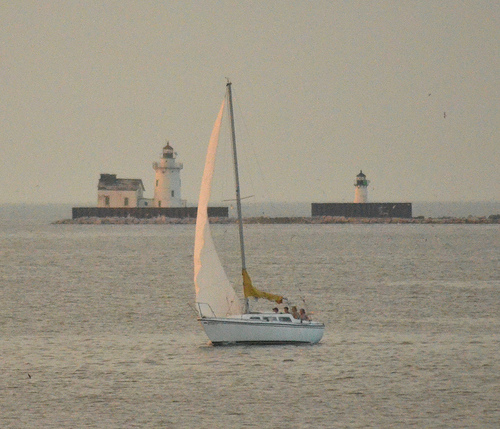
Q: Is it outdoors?
A: Yes, it is outdoors.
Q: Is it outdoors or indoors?
A: It is outdoors.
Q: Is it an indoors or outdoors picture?
A: It is outdoors.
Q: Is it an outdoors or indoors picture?
A: It is outdoors.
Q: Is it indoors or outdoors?
A: It is outdoors.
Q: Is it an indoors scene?
A: No, it is outdoors.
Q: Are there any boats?
A: Yes, there is a boat.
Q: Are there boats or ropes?
A: Yes, there is a boat.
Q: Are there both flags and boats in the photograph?
A: Yes, there are both a boat and a flag.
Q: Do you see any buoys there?
A: No, there are no buoys.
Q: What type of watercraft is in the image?
A: The watercraft is a boat.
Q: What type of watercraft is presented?
A: The watercraft is a boat.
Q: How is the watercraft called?
A: The watercraft is a boat.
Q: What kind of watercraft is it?
A: The watercraft is a boat.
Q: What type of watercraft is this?
A: This is a boat.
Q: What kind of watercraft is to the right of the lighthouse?
A: The watercraft is a boat.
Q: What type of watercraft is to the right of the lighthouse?
A: The watercraft is a boat.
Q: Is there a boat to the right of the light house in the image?
A: Yes, there is a boat to the right of the light house.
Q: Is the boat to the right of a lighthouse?
A: Yes, the boat is to the right of a lighthouse.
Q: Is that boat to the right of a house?
A: No, the boat is to the right of a lighthouse.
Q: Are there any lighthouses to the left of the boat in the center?
A: Yes, there is a lighthouse to the left of the boat.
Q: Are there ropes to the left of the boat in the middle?
A: No, there is a lighthouse to the left of the boat.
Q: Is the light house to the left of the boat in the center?
A: Yes, the light house is to the left of the boat.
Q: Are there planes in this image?
A: No, there are no planes.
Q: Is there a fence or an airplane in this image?
A: No, there are no airplanes or fences.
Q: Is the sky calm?
A: Yes, the sky is calm.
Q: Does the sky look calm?
A: Yes, the sky is calm.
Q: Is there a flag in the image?
A: Yes, there is a flag.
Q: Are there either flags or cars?
A: Yes, there is a flag.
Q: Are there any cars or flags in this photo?
A: Yes, there is a flag.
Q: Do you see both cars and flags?
A: No, there is a flag but no cars.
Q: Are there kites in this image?
A: No, there are no kites.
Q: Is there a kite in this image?
A: No, there are no kites.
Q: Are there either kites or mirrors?
A: No, there are no kites or mirrors.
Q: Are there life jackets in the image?
A: No, there are no life jackets.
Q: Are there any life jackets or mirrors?
A: No, there are no life jackets or mirrors.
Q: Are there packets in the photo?
A: No, there are no packets.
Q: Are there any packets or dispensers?
A: No, there are no packets or dispensers.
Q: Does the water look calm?
A: Yes, the water is calm.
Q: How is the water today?
A: The water is calm.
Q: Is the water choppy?
A: No, the water is calm.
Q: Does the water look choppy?
A: No, the water is calm.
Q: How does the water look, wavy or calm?
A: The water is calm.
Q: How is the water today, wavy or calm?
A: The water is calm.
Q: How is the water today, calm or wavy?
A: The water is calm.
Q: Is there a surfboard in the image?
A: No, there are no surfboards.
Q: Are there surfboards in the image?
A: No, there are no surfboards.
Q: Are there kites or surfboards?
A: No, there are no surfboards or kites.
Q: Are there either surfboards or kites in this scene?
A: No, there are no surfboards or kites.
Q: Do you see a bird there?
A: No, there are no birds.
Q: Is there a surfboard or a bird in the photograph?
A: No, there are no birds or surfboards.